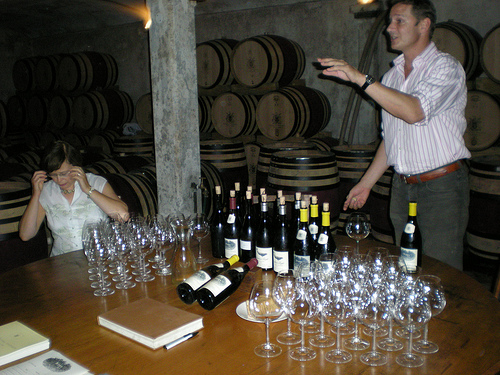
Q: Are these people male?
A: No, they are both male and female.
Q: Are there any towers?
A: No, there are no towers.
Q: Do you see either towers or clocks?
A: No, there are no towers or clocks.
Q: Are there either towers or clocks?
A: No, there are no towers or clocks.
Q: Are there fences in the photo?
A: No, there are no fences.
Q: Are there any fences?
A: No, there are no fences.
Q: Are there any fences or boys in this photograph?
A: No, there are no fences or boys.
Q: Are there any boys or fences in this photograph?
A: No, there are no fences or boys.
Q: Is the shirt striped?
A: Yes, the shirt is striped.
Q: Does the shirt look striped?
A: Yes, the shirt is striped.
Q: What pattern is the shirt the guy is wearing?
A: The shirt is striped.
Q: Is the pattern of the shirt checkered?
A: No, the shirt is striped.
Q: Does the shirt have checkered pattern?
A: No, the shirt is striped.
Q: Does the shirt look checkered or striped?
A: The shirt is striped.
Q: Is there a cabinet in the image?
A: No, there are no cabinets.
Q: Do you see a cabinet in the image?
A: No, there are no cabinets.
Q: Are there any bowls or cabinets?
A: No, there are no cabinets or bowls.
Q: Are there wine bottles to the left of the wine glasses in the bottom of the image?
A: Yes, there is a wine bottle to the left of the wine glasses.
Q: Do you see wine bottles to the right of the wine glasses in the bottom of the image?
A: No, the wine bottle is to the left of the wine glasses.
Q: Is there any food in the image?
A: No, there is no food.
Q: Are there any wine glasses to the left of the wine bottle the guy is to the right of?
A: Yes, there are wine glasses to the left of the wine bottle.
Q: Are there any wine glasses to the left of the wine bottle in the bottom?
A: Yes, there are wine glasses to the left of the wine bottle.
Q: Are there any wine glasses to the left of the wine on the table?
A: Yes, there are wine glasses to the left of the wine.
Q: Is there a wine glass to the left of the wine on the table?
A: Yes, there are wine glasses to the left of the wine.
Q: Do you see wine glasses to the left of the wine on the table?
A: Yes, there are wine glasses to the left of the wine.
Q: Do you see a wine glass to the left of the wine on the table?
A: Yes, there are wine glasses to the left of the wine.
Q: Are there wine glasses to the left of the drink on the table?
A: Yes, there are wine glasses to the left of the wine.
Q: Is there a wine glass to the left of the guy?
A: Yes, there are wine glasses to the left of the guy.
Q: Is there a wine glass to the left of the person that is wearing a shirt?
A: Yes, there are wine glasses to the left of the guy.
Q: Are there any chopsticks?
A: No, there are no chopsticks.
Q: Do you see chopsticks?
A: No, there are no chopsticks.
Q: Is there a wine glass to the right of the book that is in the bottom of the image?
A: Yes, there are wine glasses to the right of the book.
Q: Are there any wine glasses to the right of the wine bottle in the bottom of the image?
A: Yes, there are wine glasses to the right of the wine bottle.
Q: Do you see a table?
A: Yes, there is a table.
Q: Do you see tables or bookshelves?
A: Yes, there is a table.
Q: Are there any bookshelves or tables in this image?
A: Yes, there is a table.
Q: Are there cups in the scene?
A: No, there are no cups.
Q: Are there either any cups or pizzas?
A: No, there are no cups or pizzas.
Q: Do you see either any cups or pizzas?
A: No, there are no cups or pizzas.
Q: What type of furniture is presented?
A: The furniture is a table.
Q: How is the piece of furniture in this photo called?
A: The piece of furniture is a table.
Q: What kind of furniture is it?
A: The piece of furniture is a table.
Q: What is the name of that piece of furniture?
A: That is a table.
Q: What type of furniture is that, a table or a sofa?
A: That is a table.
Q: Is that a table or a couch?
A: That is a table.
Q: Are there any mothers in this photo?
A: No, there are no mothers.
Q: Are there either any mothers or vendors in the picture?
A: No, there are no mothers or vendors.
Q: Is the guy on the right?
A: Yes, the guy is on the right of the image.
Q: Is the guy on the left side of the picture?
A: No, the guy is on the right of the image.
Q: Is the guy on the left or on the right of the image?
A: The guy is on the right of the image.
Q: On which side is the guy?
A: The guy is on the right of the image.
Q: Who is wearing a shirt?
A: The guy is wearing a shirt.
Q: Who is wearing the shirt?
A: The guy is wearing a shirt.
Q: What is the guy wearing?
A: The guy is wearing a shirt.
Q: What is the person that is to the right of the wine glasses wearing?
A: The guy is wearing a shirt.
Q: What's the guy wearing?
A: The guy is wearing a shirt.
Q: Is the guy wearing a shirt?
A: Yes, the guy is wearing a shirt.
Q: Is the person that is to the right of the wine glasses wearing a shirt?
A: Yes, the guy is wearing a shirt.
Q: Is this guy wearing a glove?
A: No, the guy is wearing a shirt.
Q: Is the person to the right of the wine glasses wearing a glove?
A: No, the guy is wearing a shirt.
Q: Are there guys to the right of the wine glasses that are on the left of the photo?
A: Yes, there is a guy to the right of the wine glasses.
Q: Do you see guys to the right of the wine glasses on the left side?
A: Yes, there is a guy to the right of the wine glasses.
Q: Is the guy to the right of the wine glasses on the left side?
A: Yes, the guy is to the right of the wine glasses.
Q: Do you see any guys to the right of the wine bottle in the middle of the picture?
A: Yes, there is a guy to the right of the wine bottle.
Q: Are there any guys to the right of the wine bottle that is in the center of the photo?
A: Yes, there is a guy to the right of the wine bottle.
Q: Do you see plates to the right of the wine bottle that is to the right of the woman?
A: No, there is a guy to the right of the wine bottle.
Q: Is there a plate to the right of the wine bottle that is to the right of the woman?
A: No, there is a guy to the right of the wine bottle.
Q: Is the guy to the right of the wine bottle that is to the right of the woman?
A: Yes, the guy is to the right of the wine bottle.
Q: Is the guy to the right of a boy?
A: No, the guy is to the right of the wine bottle.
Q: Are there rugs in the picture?
A: No, there are no rugs.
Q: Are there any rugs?
A: No, there are no rugs.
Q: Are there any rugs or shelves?
A: No, there are no rugs or shelves.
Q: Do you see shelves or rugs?
A: No, there are no rugs or shelves.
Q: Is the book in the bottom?
A: Yes, the book is in the bottom of the image.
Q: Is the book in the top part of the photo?
A: No, the book is in the bottom of the image.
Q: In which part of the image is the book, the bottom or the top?
A: The book is in the bottom of the image.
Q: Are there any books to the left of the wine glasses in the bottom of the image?
A: Yes, there is a book to the left of the wine glasses.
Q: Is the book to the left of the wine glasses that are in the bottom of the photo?
A: Yes, the book is to the left of the wine glasses.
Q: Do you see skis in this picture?
A: No, there are no skis.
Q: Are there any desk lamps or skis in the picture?
A: No, there are no skis or desk lamps.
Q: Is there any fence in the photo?
A: No, there are no fences.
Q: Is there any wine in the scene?
A: Yes, there is wine.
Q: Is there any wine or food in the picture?
A: Yes, there is wine.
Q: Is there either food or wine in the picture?
A: Yes, there is wine.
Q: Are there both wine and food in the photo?
A: No, there is wine but no food.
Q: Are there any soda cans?
A: No, there are no soda cans.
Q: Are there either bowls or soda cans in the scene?
A: No, there are no soda cans or bowls.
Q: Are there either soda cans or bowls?
A: No, there are no soda cans or bowls.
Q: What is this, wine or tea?
A: This is wine.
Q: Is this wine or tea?
A: This is wine.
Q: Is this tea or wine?
A: This is wine.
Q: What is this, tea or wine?
A: This is wine.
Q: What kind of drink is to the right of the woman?
A: The drink is wine.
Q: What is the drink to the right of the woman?
A: The drink is wine.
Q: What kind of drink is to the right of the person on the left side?
A: The drink is wine.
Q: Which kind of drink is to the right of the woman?
A: The drink is wine.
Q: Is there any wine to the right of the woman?
A: Yes, there is wine to the right of the woman.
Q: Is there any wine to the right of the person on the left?
A: Yes, there is wine to the right of the woman.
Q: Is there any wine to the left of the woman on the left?
A: No, the wine is to the right of the woman.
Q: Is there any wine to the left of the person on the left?
A: No, the wine is to the right of the woman.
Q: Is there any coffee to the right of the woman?
A: No, there is wine to the right of the woman.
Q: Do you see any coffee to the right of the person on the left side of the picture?
A: No, there is wine to the right of the woman.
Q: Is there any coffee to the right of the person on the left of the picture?
A: No, there is wine to the right of the woman.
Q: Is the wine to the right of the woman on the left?
A: Yes, the wine is to the right of the woman.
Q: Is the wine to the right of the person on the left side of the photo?
A: Yes, the wine is to the right of the woman.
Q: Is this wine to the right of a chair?
A: No, the wine is to the right of the woman.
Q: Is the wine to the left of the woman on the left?
A: No, the wine is to the right of the woman.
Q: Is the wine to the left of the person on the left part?
A: No, the wine is to the right of the woman.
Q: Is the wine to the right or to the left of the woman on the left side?
A: The wine is to the right of the woman.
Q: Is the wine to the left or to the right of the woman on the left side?
A: The wine is to the right of the woman.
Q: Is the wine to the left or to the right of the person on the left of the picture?
A: The wine is to the right of the woman.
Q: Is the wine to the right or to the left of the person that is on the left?
A: The wine is to the right of the woman.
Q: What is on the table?
A: The wine is on the table.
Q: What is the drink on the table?
A: The drink is wine.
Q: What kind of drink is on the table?
A: The drink is wine.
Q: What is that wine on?
A: The wine is on the table.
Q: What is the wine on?
A: The wine is on the table.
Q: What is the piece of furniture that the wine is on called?
A: The piece of furniture is a table.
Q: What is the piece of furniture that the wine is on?
A: The piece of furniture is a table.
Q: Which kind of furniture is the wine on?
A: The wine is on the table.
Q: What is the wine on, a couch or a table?
A: The wine is on a table.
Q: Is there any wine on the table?
A: Yes, there is wine on the table.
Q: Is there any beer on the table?
A: No, there is wine on the table.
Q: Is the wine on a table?
A: Yes, the wine is on a table.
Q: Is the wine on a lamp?
A: No, the wine is on a table.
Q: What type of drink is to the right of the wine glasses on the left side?
A: The drink is wine.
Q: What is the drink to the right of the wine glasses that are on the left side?
A: The drink is wine.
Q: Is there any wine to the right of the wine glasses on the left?
A: Yes, there is wine to the right of the wine glasses.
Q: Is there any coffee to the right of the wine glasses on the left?
A: No, there is wine to the right of the wine glasses.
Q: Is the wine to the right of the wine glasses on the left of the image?
A: Yes, the wine is to the right of the wine glasses.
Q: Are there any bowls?
A: No, there are no bowls.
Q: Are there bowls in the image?
A: No, there are no bowls.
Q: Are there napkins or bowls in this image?
A: No, there are no bowls or napkins.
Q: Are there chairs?
A: No, there are no chairs.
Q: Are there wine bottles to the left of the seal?
A: Yes, there is a wine bottle to the left of the seal.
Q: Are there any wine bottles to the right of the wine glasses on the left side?
A: Yes, there is a wine bottle to the right of the wine glasses.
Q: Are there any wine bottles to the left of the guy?
A: Yes, there is a wine bottle to the left of the guy.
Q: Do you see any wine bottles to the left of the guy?
A: Yes, there is a wine bottle to the left of the guy.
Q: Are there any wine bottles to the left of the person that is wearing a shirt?
A: Yes, there is a wine bottle to the left of the guy.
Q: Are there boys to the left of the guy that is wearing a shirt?
A: No, there is a wine bottle to the left of the guy.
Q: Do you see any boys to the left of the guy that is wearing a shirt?
A: No, there is a wine bottle to the left of the guy.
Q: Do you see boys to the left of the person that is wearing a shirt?
A: No, there is a wine bottle to the left of the guy.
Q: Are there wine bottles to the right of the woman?
A: Yes, there is a wine bottle to the right of the woman.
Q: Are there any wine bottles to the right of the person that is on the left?
A: Yes, there is a wine bottle to the right of the woman.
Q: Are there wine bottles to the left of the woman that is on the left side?
A: No, the wine bottle is to the right of the woman.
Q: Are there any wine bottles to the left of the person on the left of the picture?
A: No, the wine bottle is to the right of the woman.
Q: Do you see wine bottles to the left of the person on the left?
A: No, the wine bottle is to the right of the woman.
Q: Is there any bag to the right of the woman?
A: No, there is a wine bottle to the right of the woman.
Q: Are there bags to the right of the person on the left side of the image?
A: No, there is a wine bottle to the right of the woman.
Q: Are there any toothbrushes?
A: No, there are no toothbrushes.